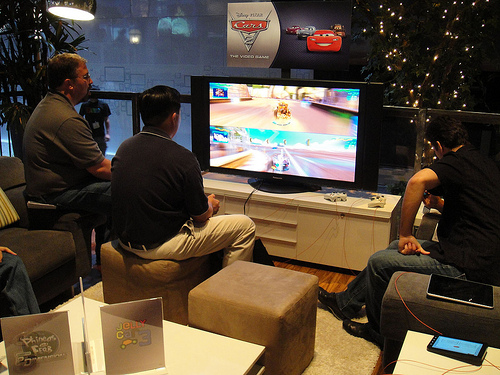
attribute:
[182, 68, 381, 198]
television — large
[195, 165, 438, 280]
stand — white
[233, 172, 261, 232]
cord — black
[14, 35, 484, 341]
people — playing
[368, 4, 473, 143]
lights — white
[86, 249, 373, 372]
rug — plush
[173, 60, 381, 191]
television — active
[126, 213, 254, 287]
pants — brown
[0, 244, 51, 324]
jeans — blue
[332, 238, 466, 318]
jeans — blue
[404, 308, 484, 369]
phone — active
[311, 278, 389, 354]
shoes — black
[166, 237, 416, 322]
floor — wooden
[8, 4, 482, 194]
wall — tiled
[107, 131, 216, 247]
shirt — black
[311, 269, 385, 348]
shoe — black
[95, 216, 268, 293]
pants — white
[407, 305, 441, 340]
cables — red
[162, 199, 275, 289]
khakis — beige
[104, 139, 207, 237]
shirt — blue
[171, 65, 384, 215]
screen tv — large, flat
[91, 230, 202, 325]
stool — tan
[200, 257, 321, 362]
stool — tan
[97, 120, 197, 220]
shirt — black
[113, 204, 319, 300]
pants — tan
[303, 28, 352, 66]
car — red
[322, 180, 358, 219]
controller — white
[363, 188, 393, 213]
controller — white